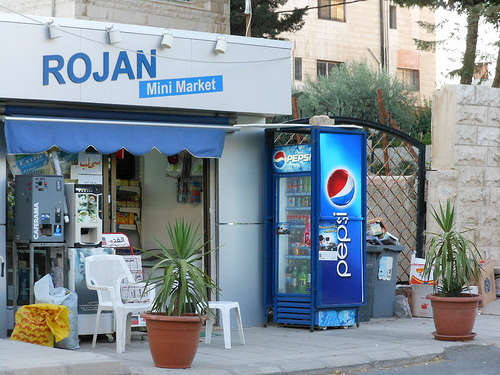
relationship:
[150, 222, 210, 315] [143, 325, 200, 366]
plant in pot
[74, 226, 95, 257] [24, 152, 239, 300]
dispenser in front of store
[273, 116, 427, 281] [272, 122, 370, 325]
door behind cooler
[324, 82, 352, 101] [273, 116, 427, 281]
bush behind door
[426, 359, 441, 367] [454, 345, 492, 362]
leaves on ground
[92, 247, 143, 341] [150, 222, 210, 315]
stool behind plant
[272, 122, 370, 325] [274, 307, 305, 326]
cooler has vent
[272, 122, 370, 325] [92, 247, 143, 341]
cooler outside stool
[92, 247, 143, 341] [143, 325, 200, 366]
stool near pot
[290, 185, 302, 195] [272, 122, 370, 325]
soda in cooler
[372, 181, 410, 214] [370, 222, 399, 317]
door behind trash can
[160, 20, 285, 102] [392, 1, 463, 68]
sign on building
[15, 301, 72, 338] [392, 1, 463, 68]
bag in front of building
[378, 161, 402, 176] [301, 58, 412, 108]
trunk of tree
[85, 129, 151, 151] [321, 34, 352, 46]
shelves on wall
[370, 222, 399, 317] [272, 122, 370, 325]
trash can behind cooler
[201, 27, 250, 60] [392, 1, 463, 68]
light on building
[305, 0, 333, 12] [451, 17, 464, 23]
line in sky